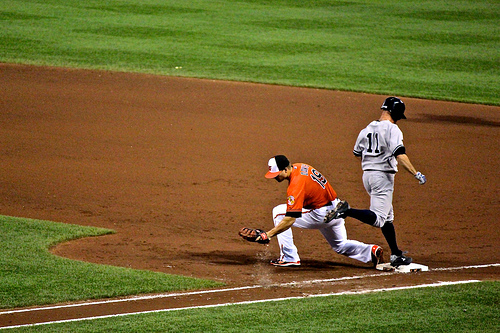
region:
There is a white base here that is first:
[383, 257, 447, 300]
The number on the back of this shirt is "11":
[365, 128, 397, 185]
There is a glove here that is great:
[247, 225, 276, 268]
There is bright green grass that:
[18, 254, 26, 279]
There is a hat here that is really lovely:
[262, 155, 292, 186]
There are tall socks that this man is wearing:
[351, 199, 379, 231]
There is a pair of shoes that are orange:
[280, 248, 307, 280]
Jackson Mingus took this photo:
[127, 65, 442, 317]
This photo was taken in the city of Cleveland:
[159, 80, 391, 288]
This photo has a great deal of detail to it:
[143, 73, 433, 270]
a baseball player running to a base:
[332, 81, 435, 267]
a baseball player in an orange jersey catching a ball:
[235, 135, 361, 275]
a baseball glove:
[232, 220, 272, 245]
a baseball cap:
[260, 142, 295, 177]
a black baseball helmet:
[375, 87, 420, 117]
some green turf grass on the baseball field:
[1, 0, 491, 55]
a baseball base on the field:
[376, 250, 431, 275]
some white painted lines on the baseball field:
[1, 280, 317, 330]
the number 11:
[356, 127, 391, 159]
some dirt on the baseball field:
[3, 58, 490, 296]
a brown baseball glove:
[233, 224, 270, 244]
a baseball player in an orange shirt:
[241, 155, 392, 272]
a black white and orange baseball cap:
[261, 151, 291, 178]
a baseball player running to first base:
[323, 95, 424, 265]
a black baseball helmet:
[379, 94, 411, 121]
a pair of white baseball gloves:
[416, 170, 425, 182]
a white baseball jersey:
[353, 118, 410, 175]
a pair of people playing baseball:
[238, 94, 426, 272]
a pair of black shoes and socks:
[382, 222, 413, 266]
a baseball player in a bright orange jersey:
[235, 155, 383, 271]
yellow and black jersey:
[285, 163, 339, 213]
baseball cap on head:
[263, 154, 290, 179]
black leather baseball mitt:
[238, 227, 267, 244]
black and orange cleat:
[268, 258, 301, 270]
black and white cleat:
[325, 200, 350, 223]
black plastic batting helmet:
[381, 97, 408, 119]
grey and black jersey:
[354, 120, 406, 172]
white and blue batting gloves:
[416, 171, 427, 183]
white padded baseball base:
[377, 259, 427, 274]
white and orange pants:
[268, 203, 375, 264]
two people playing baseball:
[233, 85, 418, 288]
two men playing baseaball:
[239, 82, 434, 292]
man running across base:
[333, 79, 437, 277]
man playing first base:
[233, 142, 340, 289]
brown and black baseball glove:
[230, 227, 271, 248]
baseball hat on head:
[261, 145, 286, 177]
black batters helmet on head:
[378, 98, 408, 124]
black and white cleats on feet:
[390, 253, 415, 268]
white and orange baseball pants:
[265, 205, 354, 275]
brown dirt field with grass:
[0, 64, 220, 286]